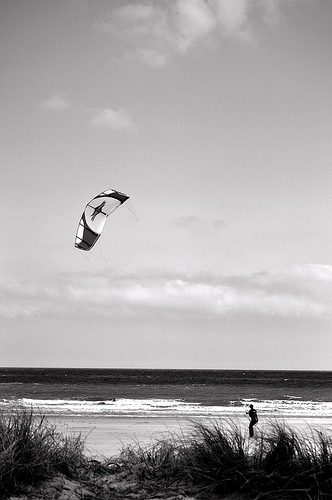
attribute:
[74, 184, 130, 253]
sail — black, white, in the sky, big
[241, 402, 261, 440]
man — black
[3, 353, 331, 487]
beach — sandy, smooth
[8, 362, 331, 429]
sea — large, water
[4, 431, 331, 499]
plants — tall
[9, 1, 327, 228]
sky — cloudy, gray, clear, blue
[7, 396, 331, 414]
waves — white, small, capped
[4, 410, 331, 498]
grass — wispy, tall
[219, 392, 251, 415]
kite string — white, thin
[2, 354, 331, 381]
horizon line — contrasting, stark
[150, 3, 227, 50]
cloud — puffy, white, transparent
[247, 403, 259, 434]
person — standing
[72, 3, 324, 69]
clouds — white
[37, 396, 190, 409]
caps — white